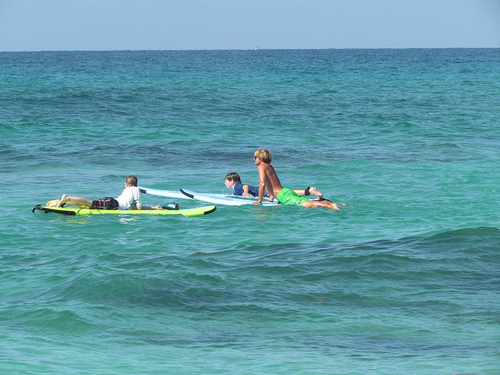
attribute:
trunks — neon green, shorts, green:
[276, 188, 313, 208]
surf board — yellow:
[28, 201, 217, 219]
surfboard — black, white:
[179, 185, 280, 208]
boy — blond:
[221, 171, 325, 197]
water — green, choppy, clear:
[6, 63, 500, 359]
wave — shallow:
[16, 218, 500, 337]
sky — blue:
[2, 2, 500, 50]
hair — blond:
[245, 149, 280, 160]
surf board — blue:
[140, 188, 262, 205]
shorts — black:
[84, 194, 119, 206]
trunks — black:
[90, 195, 123, 215]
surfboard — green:
[51, 190, 210, 231]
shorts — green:
[274, 183, 313, 209]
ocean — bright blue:
[293, 100, 453, 274]